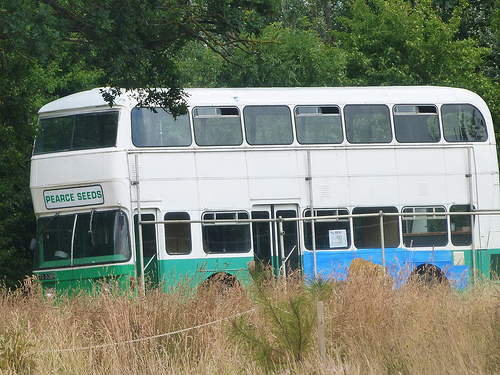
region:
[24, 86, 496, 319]
an old double-decker bus in a field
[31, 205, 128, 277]
the windshield of a bus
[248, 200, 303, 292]
the door on a bus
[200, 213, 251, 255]
a window of a bus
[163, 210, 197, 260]
a window of a bus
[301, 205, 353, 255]
a window of a bus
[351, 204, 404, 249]
a window of a bus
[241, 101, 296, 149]
a window of a bus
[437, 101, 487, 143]
a window of a bus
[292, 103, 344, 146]
a window of a bus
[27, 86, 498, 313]
bus has 2 levels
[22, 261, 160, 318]
front of bus is green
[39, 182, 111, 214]
green letters on bus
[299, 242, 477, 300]
side of bus is blue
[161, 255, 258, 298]
side of bus is green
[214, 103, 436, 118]
bus windows are open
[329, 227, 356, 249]
white sign on the bus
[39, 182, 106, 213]
black line around the words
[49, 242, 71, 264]
white object in the bus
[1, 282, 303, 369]
white wire in the grass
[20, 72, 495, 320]
a large double decker bus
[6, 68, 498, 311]
this is a double ducker bus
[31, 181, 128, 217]
this sign says "Pearce Seeds"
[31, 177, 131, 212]
the words are green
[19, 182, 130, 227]
the letters are green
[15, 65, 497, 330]
the bus has two levels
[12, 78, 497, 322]
the bus is painted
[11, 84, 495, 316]
the bus is painted in three colors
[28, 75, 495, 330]
the bus is white, green, and blue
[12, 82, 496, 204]
the top half of the bus is green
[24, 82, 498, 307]
white, blue, and green bus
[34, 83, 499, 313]
double decker bus facing left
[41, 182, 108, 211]
green letters on white sign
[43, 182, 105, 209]
Pearce Seeds sign on front of bus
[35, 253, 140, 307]
green bumper in front of bus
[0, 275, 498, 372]
beige and yellow grass in front of bus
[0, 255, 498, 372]
overgrown grass in front of bus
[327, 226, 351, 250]
white notice on bus window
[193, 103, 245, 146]
window open in top right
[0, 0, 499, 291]
lush green trees behind bus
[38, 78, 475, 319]
large two story bus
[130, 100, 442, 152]
windows on side of bus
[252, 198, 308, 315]
door on side of bus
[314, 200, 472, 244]
windows on side of bus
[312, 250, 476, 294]
blue bottom of bus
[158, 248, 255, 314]
green bottom of bus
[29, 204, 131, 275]
front windshield of bus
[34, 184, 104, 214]
white sign on front of bus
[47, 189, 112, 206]
green writing on front of sign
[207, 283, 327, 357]
green bush growing on ground